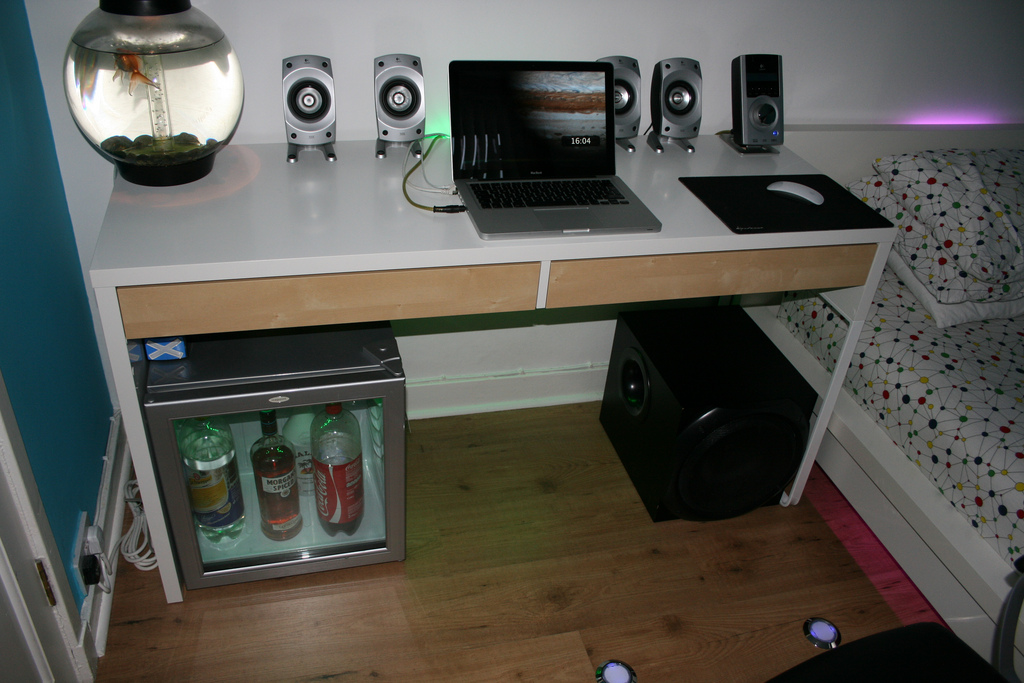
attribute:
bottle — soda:
[173, 415, 243, 543]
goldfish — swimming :
[110, 53, 147, 82]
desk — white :
[132, 206, 463, 258]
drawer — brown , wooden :
[303, 299, 321, 310]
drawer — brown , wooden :
[627, 269, 649, 287]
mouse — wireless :
[773, 180, 832, 209]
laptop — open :
[452, 57, 664, 235]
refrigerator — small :
[128, 333, 418, 582]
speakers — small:
[280, 46, 469, 198]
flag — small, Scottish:
[135, 318, 224, 375]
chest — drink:
[234, 392, 355, 567]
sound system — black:
[595, 331, 779, 524]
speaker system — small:
[217, 18, 840, 166]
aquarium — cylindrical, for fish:
[68, 38, 289, 203]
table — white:
[243, 185, 386, 270]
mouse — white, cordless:
[755, 156, 823, 230]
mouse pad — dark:
[695, 159, 754, 231]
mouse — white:
[768, 165, 840, 230]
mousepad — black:
[697, 163, 784, 263]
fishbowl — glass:
[74, 40, 262, 203]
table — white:
[247, 197, 414, 267]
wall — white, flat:
[818, 37, 979, 174]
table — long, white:
[178, 208, 397, 275]